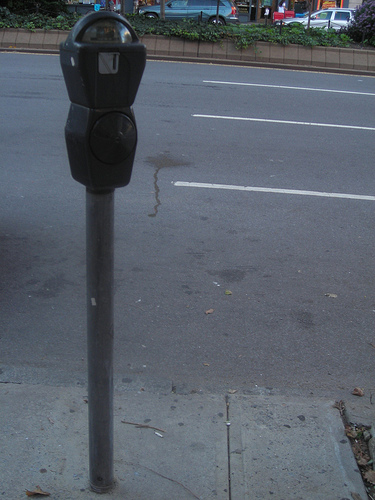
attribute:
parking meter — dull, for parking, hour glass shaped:
[56, 12, 146, 190]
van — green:
[136, 2, 234, 23]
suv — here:
[279, 8, 353, 32]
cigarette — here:
[152, 427, 162, 439]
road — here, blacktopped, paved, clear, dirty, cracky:
[3, 49, 373, 394]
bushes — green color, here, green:
[1, 8, 372, 49]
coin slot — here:
[111, 50, 117, 71]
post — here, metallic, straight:
[83, 185, 114, 494]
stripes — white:
[177, 80, 373, 204]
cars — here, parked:
[141, 0, 358, 34]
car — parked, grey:
[279, 7, 355, 32]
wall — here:
[1, 29, 373, 75]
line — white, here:
[168, 176, 374, 205]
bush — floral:
[345, 2, 374, 38]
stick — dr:
[119, 417, 164, 430]